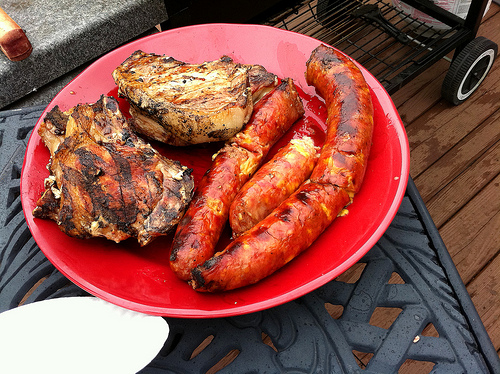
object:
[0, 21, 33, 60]
tool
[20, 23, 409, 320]
plate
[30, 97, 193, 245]
chicken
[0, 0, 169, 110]
counter top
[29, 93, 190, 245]
meat type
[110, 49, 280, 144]
meat type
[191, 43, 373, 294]
meat type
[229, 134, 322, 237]
meat type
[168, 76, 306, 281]
meat type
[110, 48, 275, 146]
meat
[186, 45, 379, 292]
sausage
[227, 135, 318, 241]
sausage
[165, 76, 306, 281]
sausage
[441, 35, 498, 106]
grill tire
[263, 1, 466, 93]
basket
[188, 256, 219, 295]
mark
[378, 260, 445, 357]
vehicle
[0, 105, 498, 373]
table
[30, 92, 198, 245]
meat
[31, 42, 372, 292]
food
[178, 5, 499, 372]
floor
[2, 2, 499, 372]
photo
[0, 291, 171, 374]
plate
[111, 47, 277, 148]
chicken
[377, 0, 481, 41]
propane tank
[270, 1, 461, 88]
grill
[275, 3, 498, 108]
cart